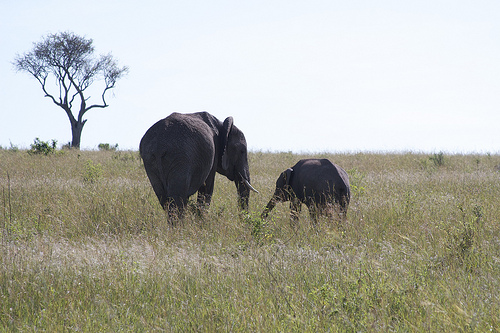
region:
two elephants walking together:
[130, 90, 376, 255]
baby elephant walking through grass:
[267, 150, 369, 255]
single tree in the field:
[17, 21, 107, 163]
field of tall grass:
[5, 140, 495, 326]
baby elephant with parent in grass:
[121, 107, 406, 249]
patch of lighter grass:
[24, 221, 342, 313]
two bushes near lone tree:
[11, 134, 126, 159]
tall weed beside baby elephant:
[341, 156, 379, 216]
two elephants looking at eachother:
[133, 108, 373, 242]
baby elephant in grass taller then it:
[261, 153, 391, 258]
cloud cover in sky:
[0, 2, 499, 150]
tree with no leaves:
[16, 30, 118, 148]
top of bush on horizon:
[97, 142, 119, 152]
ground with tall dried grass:
[2, 151, 495, 331]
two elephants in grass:
[137, 110, 349, 230]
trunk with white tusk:
[235, 171, 255, 213]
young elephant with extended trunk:
[263, 155, 350, 230]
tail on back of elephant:
[148, 148, 172, 189]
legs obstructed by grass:
[160, 189, 216, 232]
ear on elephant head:
[218, 115, 236, 170]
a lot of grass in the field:
[3, 260, 496, 325]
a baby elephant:
[268, 155, 351, 227]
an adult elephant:
[147, 112, 255, 227]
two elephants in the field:
[138, 114, 350, 251]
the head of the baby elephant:
[276, 167, 289, 203]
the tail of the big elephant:
[153, 146, 168, 187]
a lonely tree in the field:
[18, 35, 125, 147]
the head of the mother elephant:
[221, 119, 257, 194]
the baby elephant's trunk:
[258, 194, 282, 236]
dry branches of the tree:
[11, 33, 126, 90]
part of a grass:
[411, 240, 428, 264]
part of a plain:
[331, 253, 346, 304]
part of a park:
[243, 280, 255, 300]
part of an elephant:
[328, 194, 333, 213]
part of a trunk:
[271, 207, 282, 216]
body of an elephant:
[191, 143, 197, 153]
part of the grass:
[404, 207, 418, 227]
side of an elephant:
[190, 140, 197, 149]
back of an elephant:
[159, 130, 179, 167]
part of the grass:
[238, 290, 253, 305]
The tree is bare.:
[22, 28, 112, 157]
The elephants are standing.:
[122, 110, 372, 235]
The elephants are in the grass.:
[133, 100, 374, 243]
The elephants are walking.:
[135, 100, 360, 241]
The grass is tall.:
[12, 150, 496, 308]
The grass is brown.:
[3, 146, 499, 325]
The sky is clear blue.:
[5, 5, 499, 153]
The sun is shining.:
[13, 14, 482, 331]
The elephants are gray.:
[110, 92, 367, 220]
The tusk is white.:
[240, 170, 263, 195]